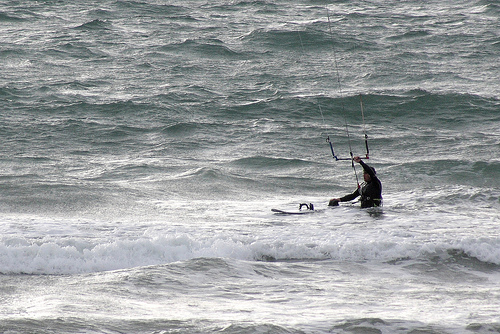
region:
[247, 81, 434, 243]
man surfing in ocean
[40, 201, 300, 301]
waves breaking in ocean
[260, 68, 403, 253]
man holding onto glider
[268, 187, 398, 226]
surf board in ocean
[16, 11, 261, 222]
blue ocean with waves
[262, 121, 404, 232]
man looking out into ocean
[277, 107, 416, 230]
male surfer in black wet suit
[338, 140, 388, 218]
man in black wet suit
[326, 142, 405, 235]
person wearing black wet suit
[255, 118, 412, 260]
surfer wearing black wet suit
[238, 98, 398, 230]
one man is wind boarding in water.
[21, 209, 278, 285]
Waves are white color.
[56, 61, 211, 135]
Water is blue color.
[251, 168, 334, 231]
Wind board is black color.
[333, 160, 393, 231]
Man is in black suit.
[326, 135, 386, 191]
Man is holding the rod in left hand.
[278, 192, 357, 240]
In right hand the man is holding wind board.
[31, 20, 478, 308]
Day time picture.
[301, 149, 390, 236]
Man is standing in water.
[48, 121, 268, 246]
Sun light reflection is seen in water.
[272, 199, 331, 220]
board floating on water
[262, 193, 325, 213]
board without someone in it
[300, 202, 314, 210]
empty foot strap of board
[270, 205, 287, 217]
raised edge of board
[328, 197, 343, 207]
hand holding the board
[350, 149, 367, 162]
hand holding kite handle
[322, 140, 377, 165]
black kite handle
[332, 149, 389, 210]
man standing in water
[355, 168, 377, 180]
head of man in water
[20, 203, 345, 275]
waves crashing into white caps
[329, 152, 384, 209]
person standing in water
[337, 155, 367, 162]
person holding bar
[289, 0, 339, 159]
cable attached to bar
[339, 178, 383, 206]
person wearing a black wet suit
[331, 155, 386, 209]
person is wet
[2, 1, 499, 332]
water under person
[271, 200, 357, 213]
surfboard to the left of person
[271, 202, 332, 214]
surfboard on the water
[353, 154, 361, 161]
hand on bar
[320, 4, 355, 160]
cable to the right of cable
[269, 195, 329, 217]
board floating in water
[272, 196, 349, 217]
board is not occupied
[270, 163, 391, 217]
man in water by board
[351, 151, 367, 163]
left hand of person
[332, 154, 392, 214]
person in wavy water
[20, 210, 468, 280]
white capped waves in water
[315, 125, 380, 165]
metal pole in air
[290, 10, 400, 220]
person holding onto kite thing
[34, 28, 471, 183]
grey and wavy water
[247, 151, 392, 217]
person holding on to board